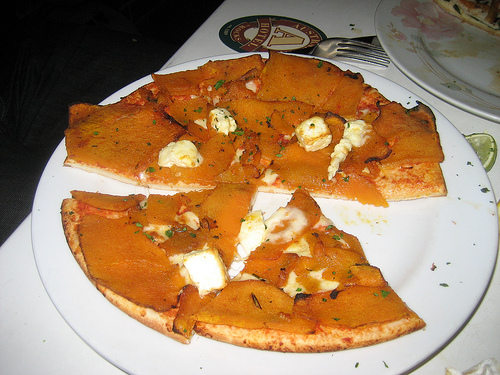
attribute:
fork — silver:
[308, 35, 391, 67]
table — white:
[2, 1, 498, 374]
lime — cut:
[464, 133, 496, 171]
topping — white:
[158, 109, 372, 297]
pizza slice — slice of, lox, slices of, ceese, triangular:
[195, 187, 425, 353]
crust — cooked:
[197, 312, 428, 352]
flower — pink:
[392, 3, 466, 39]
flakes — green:
[427, 145, 500, 295]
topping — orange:
[77, 214, 186, 311]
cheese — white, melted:
[157, 140, 204, 170]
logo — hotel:
[217, 15, 326, 54]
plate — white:
[34, 43, 479, 373]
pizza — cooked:
[62, 66, 451, 366]